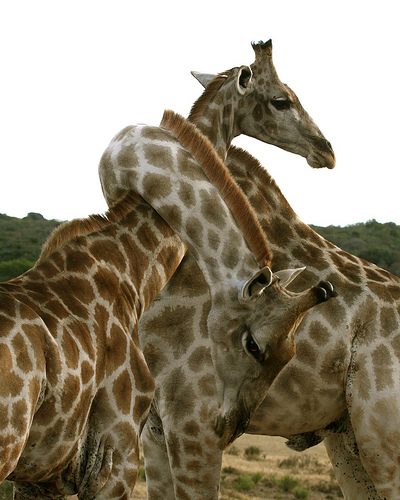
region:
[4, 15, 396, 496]
two giraffe in the wild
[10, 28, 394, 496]
one giraffe wrapping its neck around another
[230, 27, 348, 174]
the head of a giraffe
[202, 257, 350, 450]
the head of a giraffe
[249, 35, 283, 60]
the horns of a giraffe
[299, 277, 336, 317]
the horns of a giraffe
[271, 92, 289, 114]
the eye of a giraffe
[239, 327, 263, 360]
the eye of a giraffe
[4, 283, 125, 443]
the spots of a giraffe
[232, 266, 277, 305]
the ear of a giraffe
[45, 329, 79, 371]
Brown spot on a giraffe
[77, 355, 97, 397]
Brown spot on a giraffe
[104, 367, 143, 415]
Brown spot on a giraffe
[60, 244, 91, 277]
Brown spot on a giraffe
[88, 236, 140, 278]
Brown spot on a giraffe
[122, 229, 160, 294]
Brown spot on a giraffe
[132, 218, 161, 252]
Brown spot on a giraffe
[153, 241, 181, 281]
Brown spot on a giraffe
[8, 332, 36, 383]
Brown spot on a giraffe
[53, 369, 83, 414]
Brown spot on a giraffe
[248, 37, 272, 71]
giraffe's horn-like ossicones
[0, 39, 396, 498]
two male giraffes fighting for dominance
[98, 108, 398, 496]
male giraffe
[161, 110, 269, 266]
light brown short bristly giraffe main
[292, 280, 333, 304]
bone-like male giraffe ossicones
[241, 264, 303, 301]
giraffe ears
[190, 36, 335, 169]
giraffe ears pointed backward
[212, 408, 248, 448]
giraffe snout with prehensile upper lip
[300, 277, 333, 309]
bald-topped male giraffe ossicones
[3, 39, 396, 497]
male giraffes fighting by necking, wrapping their necks around the other's necks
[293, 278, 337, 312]
Twin horns of a giraffe with black ends and tan bottoms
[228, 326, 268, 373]
Large dark colored eye of a giraffe looking down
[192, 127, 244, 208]
Brown colored thick mane of a giraffe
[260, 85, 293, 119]
Open black eye of a giraffe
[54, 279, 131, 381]
Spotted side of a giraffe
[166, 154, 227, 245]
Long giraffe's neck bending over and looking down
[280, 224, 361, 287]
Brown spots of a giraffe with tan lines in between them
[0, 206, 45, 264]
Rocky green hill side beyond a giraffe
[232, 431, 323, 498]
Sandy ground patched with tufts of grass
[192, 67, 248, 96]
White and brown ears of a giraffe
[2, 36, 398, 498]
two giraffes standing up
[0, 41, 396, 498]
two giraffes are hugging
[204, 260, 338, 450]
one giraffe is looking down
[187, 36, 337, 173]
one giraffe is looking straight ahead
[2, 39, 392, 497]
the giraffes have patterns on them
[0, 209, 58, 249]
the trees are behind the giraffes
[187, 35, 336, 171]
the giraffe has horns on its head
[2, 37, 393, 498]
the giraffes are on the sand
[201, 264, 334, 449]
this giraffe is sleeping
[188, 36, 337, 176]
this giraffe is keeping watch